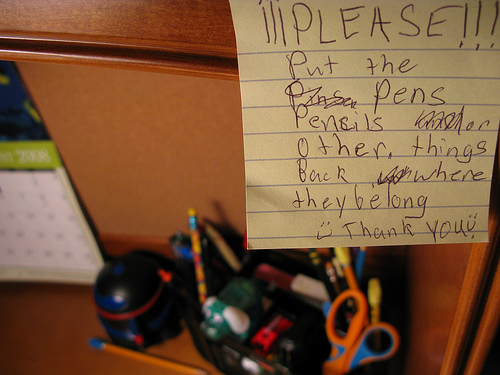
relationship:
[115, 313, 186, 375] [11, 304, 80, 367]
pencil on table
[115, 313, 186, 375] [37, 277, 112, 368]
pencil on desk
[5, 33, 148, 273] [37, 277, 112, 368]
calender on desk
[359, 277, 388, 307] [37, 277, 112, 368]
eraser on desk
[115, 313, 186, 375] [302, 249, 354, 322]
pencil and pen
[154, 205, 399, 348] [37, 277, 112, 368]
supplies on desk